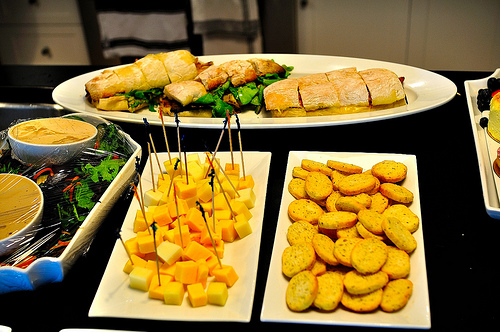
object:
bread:
[83, 69, 126, 101]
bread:
[163, 80, 207, 106]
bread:
[262, 66, 405, 115]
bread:
[300, 159, 334, 173]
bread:
[371, 160, 406, 184]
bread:
[337, 174, 376, 195]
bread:
[288, 178, 306, 199]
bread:
[305, 171, 333, 200]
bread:
[326, 191, 342, 212]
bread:
[353, 192, 372, 207]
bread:
[382, 216, 417, 253]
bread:
[355, 222, 384, 241]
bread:
[286, 220, 317, 245]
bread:
[312, 233, 339, 265]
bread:
[350, 238, 389, 275]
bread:
[380, 249, 410, 279]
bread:
[311, 261, 327, 276]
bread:
[284, 271, 317, 311]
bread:
[314, 272, 344, 312]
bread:
[341, 268, 387, 295]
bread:
[370, 173, 380, 196]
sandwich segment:
[83, 85, 164, 110]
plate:
[50, 51, 460, 131]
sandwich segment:
[188, 57, 213, 78]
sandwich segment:
[160, 73, 282, 115]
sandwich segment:
[272, 102, 309, 118]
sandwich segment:
[306, 103, 372, 115]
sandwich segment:
[371, 98, 407, 110]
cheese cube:
[164, 157, 182, 178]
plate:
[87, 149, 273, 323]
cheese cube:
[205, 157, 221, 176]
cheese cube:
[203, 164, 221, 177]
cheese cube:
[172, 174, 185, 182]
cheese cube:
[215, 177, 224, 184]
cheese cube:
[222, 175, 239, 182]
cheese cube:
[238, 176, 253, 189]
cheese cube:
[216, 174, 225, 183]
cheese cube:
[197, 186, 218, 203]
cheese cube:
[159, 196, 172, 205]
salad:
[2, 114, 132, 266]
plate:
[0, 112, 142, 289]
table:
[1, 62, 498, 330]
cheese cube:
[157, 175, 171, 189]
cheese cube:
[158, 184, 169, 191]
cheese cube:
[184, 197, 199, 207]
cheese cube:
[183, 197, 197, 211]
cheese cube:
[197, 178, 210, 189]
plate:
[260, 150, 433, 329]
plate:
[462, 67, 499, 218]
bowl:
[6, 117, 99, 167]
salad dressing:
[9, 118, 94, 143]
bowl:
[0, 173, 45, 253]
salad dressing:
[1, 175, 39, 239]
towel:
[96, 11, 190, 59]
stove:
[76, 1, 309, 68]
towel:
[190, 0, 263, 54]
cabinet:
[0, 1, 266, 66]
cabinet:
[297, 2, 498, 72]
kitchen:
[0, 0, 498, 330]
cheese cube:
[169, 216, 185, 229]